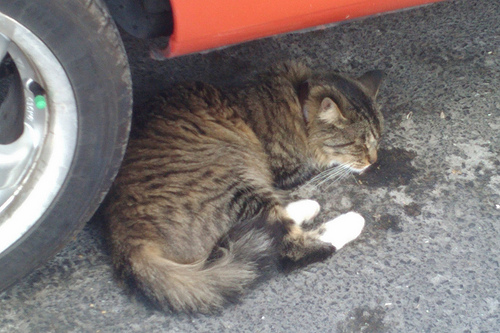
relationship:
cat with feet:
[102, 59, 386, 316] [285, 199, 320, 225]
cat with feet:
[138, 42, 451, 297] [275, 190, 378, 263]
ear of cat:
[316, 94, 348, 127] [102, 59, 386, 316]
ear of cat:
[358, 67, 387, 102] [102, 59, 386, 316]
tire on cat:
[8, 0, 128, 291] [102, 59, 386, 316]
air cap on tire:
[26, 74, 49, 113] [8, 0, 128, 291]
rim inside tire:
[1, 12, 78, 254] [8, 0, 128, 291]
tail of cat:
[126, 229, 276, 315] [102, 59, 386, 316]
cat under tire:
[102, 59, 386, 316] [0, 0, 132, 295]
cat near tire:
[102, 59, 386, 316] [0, 0, 132, 295]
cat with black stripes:
[102, 59, 386, 316] [167, 156, 235, 218]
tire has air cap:
[0, 0, 132, 295] [34, 95, 47, 110]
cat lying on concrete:
[102, 59, 386, 316] [165, 8, 488, 331]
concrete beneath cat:
[11, 24, 496, 324] [162, 70, 365, 295]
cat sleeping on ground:
[102, 59, 386, 316] [388, 47, 468, 249]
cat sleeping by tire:
[102, 59, 386, 316] [0, 0, 132, 295]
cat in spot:
[102, 59, 386, 316] [357, 128, 417, 191]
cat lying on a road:
[102, 59, 386, 316] [0, 4, 497, 330]